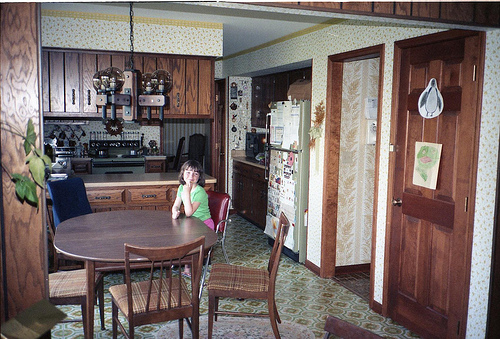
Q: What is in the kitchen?
A: Brown table top.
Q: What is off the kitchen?
A: The brown door.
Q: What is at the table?
A: The brown cushioned chair.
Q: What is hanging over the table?
A: Modern design light fixtures.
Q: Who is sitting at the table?
A: A girl.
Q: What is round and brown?
A: Table.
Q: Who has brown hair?
A: The girl.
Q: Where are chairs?
A: Around the table.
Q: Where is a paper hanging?
A: On the door.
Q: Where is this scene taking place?
A: Kitchen.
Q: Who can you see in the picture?
A: Little girl.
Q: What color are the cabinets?
A: Dark maple.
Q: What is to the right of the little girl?
A: Refrigerator.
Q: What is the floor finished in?
A: Linoleum.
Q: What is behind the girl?
A: Island.